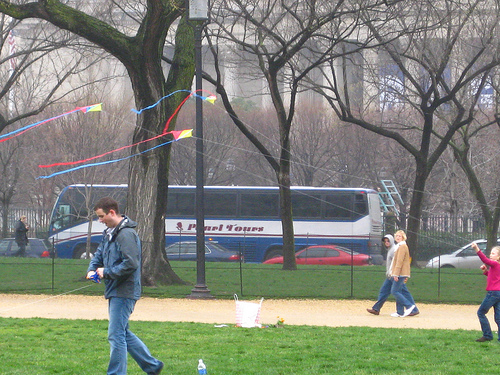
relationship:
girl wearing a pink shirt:
[467, 236, 499, 348] [481, 262, 498, 285]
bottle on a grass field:
[195, 353, 207, 373] [0, 318, 499, 368]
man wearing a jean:
[85, 197, 164, 374] [101, 295, 163, 373]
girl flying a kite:
[467, 236, 499, 348] [40, 53, 287, 230]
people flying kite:
[32, 166, 499, 373] [39, 81, 305, 211]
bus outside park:
[48, 178, 390, 260] [1, 255, 498, 372]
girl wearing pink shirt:
[467, 236, 499, 348] [468, 235, 498, 295]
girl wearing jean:
[467, 236, 499, 348] [476, 291, 498, 345]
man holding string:
[85, 197, 164, 374] [1, 272, 105, 317]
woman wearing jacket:
[382, 230, 424, 312] [394, 237, 414, 280]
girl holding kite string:
[467, 236, 499, 348] [107, 99, 499, 254]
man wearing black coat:
[85, 197, 164, 374] [85, 187, 158, 372]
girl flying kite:
[467, 236, 499, 348] [56, 89, 221, 158]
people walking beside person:
[3, 166, 498, 373] [367, 232, 417, 314]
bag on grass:
[225, 287, 270, 330] [2, 246, 497, 370]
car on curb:
[261, 242, 381, 272] [415, 257, 428, 271]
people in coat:
[3, 166, 498, 373] [387, 242, 420, 282]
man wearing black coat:
[85, 197, 164, 374] [85, 218, 158, 303]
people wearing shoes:
[3, 166, 498, 373] [388, 302, 425, 321]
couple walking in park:
[362, 227, 425, 324] [6, 3, 497, 373]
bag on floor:
[225, 287, 270, 330] [5, 245, 471, 373]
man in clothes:
[85, 197, 164, 374] [89, 213, 169, 368]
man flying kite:
[85, 197, 164, 374] [68, 101, 106, 122]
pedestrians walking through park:
[364, 226, 421, 326] [6, 3, 497, 373]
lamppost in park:
[171, 6, 235, 291] [6, 3, 497, 373]